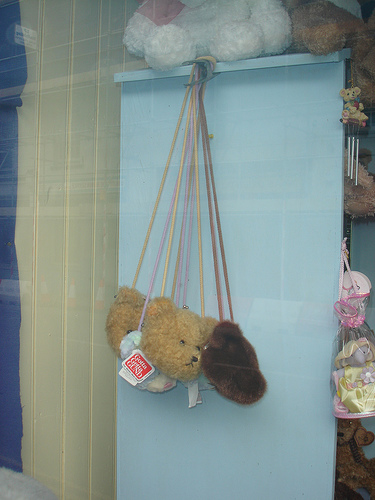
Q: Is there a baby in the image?
A: No, there are no babies.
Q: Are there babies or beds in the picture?
A: No, there are no babies or beds.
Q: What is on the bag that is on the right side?
A: The stuffed animal is on the bag.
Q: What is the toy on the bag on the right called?
A: The toy is a stuffed animal.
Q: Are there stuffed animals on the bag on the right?
A: Yes, there is a stuffed animal on the bag.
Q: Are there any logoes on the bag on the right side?
A: No, there is a stuffed animal on the bag.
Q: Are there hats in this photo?
A: Yes, there is a hat.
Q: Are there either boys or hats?
A: Yes, there is a hat.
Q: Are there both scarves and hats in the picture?
A: No, there is a hat but no scarves.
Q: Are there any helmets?
A: No, there are no helmets.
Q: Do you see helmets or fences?
A: No, there are no helmets or fences.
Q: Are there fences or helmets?
A: No, there are no helmets or fences.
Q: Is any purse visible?
A: Yes, there is a purse.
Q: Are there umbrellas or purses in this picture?
A: Yes, there is a purse.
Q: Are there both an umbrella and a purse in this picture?
A: No, there is a purse but no umbrellas.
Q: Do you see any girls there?
A: No, there are no girls.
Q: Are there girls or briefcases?
A: No, there are no girls or briefcases.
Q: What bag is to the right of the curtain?
A: The bag is a purse.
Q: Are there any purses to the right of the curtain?
A: Yes, there is a purse to the right of the curtain.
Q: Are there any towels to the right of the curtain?
A: No, there is a purse to the right of the curtain.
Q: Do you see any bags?
A: Yes, there is a bag.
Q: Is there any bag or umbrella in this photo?
A: Yes, there is a bag.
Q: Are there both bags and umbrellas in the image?
A: No, there is a bag but no umbrellas.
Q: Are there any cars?
A: No, there are no cars.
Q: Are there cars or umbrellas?
A: No, there are no cars or umbrellas.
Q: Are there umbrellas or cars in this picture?
A: No, there are no cars or umbrellas.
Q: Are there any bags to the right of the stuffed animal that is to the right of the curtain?
A: Yes, there is a bag to the right of the stuffed animal.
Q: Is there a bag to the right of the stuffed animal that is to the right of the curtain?
A: Yes, there is a bag to the right of the stuffed animal.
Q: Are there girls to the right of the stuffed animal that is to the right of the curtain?
A: No, there is a bag to the right of the stuffed animal.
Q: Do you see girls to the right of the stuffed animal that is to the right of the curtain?
A: No, there is a bag to the right of the stuffed animal.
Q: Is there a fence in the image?
A: No, there are no fences.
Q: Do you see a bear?
A: Yes, there is a bear.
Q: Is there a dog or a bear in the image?
A: Yes, there is a bear.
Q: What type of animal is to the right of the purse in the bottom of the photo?
A: The animal is a bear.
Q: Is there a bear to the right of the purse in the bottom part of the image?
A: Yes, there is a bear to the right of the purse.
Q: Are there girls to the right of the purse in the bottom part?
A: No, there is a bear to the right of the purse.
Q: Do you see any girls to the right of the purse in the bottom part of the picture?
A: No, there is a bear to the right of the purse.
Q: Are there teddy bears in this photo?
A: Yes, there is a teddy bear.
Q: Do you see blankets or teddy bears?
A: Yes, there is a teddy bear.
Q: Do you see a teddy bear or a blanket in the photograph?
A: Yes, there is a teddy bear.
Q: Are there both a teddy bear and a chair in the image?
A: No, there is a teddy bear but no chairs.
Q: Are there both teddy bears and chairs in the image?
A: No, there is a teddy bear but no chairs.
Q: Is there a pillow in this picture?
A: No, there are no pillows.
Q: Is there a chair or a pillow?
A: No, there are no pillows or chairs.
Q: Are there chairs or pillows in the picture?
A: No, there are no pillows or chairs.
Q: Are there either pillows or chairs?
A: No, there are no pillows or chairs.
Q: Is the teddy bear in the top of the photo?
A: Yes, the teddy bear is in the top of the image.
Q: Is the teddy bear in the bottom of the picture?
A: No, the teddy bear is in the top of the image.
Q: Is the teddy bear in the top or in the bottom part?
A: The teddy bear is in the top of the image.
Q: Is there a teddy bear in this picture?
A: Yes, there is a teddy bear.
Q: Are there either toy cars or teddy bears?
A: Yes, there is a teddy bear.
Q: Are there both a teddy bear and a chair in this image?
A: No, there is a teddy bear but no chairs.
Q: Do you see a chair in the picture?
A: No, there are no chairs.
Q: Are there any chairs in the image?
A: No, there are no chairs.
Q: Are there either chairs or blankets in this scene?
A: No, there are no chairs or blankets.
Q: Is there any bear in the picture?
A: Yes, there is a bear.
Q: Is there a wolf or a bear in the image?
A: Yes, there is a bear.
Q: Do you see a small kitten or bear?
A: Yes, there is a small bear.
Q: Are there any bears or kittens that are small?
A: Yes, the bear is small.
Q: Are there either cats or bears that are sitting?
A: Yes, the bear is sitting.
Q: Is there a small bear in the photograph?
A: Yes, there is a small bear.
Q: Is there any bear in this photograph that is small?
A: Yes, there is a bear that is small.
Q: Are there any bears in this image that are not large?
A: Yes, there is a small bear.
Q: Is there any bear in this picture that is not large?
A: Yes, there is a small bear.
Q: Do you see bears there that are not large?
A: Yes, there is a small bear.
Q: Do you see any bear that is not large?
A: Yes, there is a small bear.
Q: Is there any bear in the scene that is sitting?
A: Yes, there is a bear that is sitting.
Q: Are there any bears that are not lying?
A: Yes, there is a bear that is sitting.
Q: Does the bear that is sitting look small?
A: Yes, the bear is small.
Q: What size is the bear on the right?
A: The bear is small.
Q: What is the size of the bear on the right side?
A: The bear is small.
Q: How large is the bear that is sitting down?
A: The bear is small.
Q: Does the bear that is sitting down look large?
A: No, the bear is small.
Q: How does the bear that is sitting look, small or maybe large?
A: The bear is small.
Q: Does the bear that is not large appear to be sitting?
A: Yes, the bear is sitting.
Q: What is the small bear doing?
A: The bear is sitting.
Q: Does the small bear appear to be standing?
A: No, the bear is sitting.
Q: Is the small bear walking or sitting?
A: The bear is sitting.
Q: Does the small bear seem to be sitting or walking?
A: The bear is sitting.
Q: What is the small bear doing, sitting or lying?
A: The bear is sitting.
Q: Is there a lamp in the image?
A: No, there are no lamps.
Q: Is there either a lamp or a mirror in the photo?
A: No, there are no lamps or mirrors.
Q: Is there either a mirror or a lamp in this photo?
A: No, there are no lamps or mirrors.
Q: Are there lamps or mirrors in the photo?
A: No, there are no lamps or mirrors.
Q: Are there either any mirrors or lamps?
A: No, there are no lamps or mirrors.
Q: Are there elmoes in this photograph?
A: No, there are no elmoes.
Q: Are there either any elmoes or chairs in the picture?
A: No, there are no elmoes or chairs.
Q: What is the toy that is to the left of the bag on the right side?
A: The toy is a stuffed animal.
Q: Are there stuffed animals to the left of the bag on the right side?
A: Yes, there is a stuffed animal to the left of the bag.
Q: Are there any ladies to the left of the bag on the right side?
A: No, there is a stuffed animal to the left of the bag.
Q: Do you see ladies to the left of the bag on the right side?
A: No, there is a stuffed animal to the left of the bag.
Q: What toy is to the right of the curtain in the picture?
A: The toy is a stuffed animal.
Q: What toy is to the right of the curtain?
A: The toy is a stuffed animal.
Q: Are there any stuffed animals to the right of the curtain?
A: Yes, there is a stuffed animal to the right of the curtain.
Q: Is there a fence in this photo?
A: No, there are no fences.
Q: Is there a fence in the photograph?
A: No, there are no fences.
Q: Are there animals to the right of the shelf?
A: Yes, there are animals to the right of the shelf.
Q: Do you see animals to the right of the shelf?
A: Yes, there are animals to the right of the shelf.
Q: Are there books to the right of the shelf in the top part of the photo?
A: No, there are animals to the right of the shelf.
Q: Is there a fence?
A: No, there are no fences.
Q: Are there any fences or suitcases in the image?
A: No, there are no fences or suitcases.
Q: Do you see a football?
A: No, there are no footballs.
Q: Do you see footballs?
A: No, there are no footballs.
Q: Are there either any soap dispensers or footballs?
A: No, there are no footballs or soap dispensers.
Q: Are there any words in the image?
A: Yes, there are words.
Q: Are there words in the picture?
A: Yes, there are words.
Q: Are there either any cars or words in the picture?
A: Yes, there are words.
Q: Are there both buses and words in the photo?
A: No, there are words but no buses.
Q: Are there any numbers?
A: No, there are no numbers.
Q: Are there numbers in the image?
A: No, there are no numbers.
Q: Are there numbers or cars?
A: No, there are no numbers or cars.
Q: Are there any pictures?
A: No, there are no pictures.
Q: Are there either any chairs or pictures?
A: No, there are no pictures or chairs.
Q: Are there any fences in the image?
A: No, there are no fences.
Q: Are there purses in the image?
A: Yes, there is a purse.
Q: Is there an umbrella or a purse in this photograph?
A: Yes, there is a purse.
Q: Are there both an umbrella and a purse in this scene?
A: No, there is a purse but no umbrellas.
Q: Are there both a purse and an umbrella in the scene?
A: No, there is a purse but no umbrellas.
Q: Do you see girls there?
A: No, there are no girls.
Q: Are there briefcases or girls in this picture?
A: No, there are no girls or briefcases.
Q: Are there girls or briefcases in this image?
A: No, there are no girls or briefcases.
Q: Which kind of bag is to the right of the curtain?
A: The bag is a purse.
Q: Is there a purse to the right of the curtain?
A: Yes, there is a purse to the right of the curtain.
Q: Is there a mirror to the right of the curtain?
A: No, there is a purse to the right of the curtain.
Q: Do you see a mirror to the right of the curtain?
A: No, there is a purse to the right of the curtain.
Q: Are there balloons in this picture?
A: No, there are no balloons.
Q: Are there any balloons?
A: No, there are no balloons.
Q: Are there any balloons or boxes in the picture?
A: No, there are no balloons or boxes.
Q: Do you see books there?
A: No, there are no books.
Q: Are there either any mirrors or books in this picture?
A: No, there are no books or mirrors.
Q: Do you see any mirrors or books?
A: No, there are no books or mirrors.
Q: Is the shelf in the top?
A: Yes, the shelf is in the top of the image.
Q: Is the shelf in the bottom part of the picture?
A: No, the shelf is in the top of the image.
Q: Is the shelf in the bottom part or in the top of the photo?
A: The shelf is in the top of the image.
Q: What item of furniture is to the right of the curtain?
A: The piece of furniture is a shelf.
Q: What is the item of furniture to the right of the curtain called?
A: The piece of furniture is a shelf.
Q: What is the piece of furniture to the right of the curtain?
A: The piece of furniture is a shelf.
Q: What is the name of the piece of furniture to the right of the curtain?
A: The piece of furniture is a shelf.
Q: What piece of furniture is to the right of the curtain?
A: The piece of furniture is a shelf.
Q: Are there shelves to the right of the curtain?
A: Yes, there is a shelf to the right of the curtain.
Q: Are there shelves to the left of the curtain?
A: No, the shelf is to the right of the curtain.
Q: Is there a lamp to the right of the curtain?
A: No, there is a shelf to the right of the curtain.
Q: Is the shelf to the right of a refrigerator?
A: No, the shelf is to the right of the curtain.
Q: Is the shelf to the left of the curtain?
A: No, the shelf is to the right of the curtain.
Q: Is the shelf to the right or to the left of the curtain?
A: The shelf is to the right of the curtain.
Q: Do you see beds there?
A: No, there are no beds.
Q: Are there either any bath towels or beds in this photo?
A: No, there are no beds or bath towels.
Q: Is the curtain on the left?
A: Yes, the curtain is on the left of the image.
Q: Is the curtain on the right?
A: No, the curtain is on the left of the image.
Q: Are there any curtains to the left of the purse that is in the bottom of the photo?
A: Yes, there is a curtain to the left of the purse.